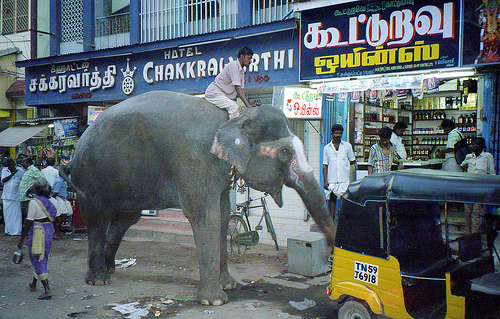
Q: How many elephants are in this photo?
A: One.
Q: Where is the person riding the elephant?
A: On the elephant's back.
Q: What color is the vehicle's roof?
A: Black.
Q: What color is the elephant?
A: Gray.